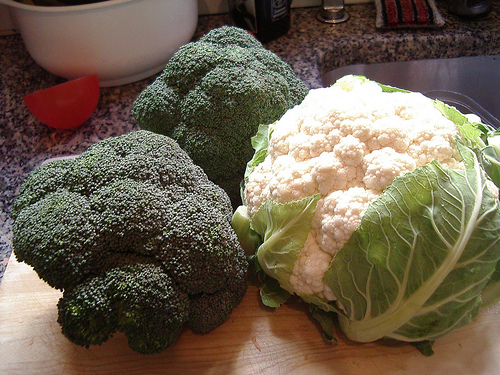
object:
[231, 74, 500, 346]
cauliflower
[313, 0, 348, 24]
dispensor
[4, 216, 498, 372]
board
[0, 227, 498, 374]
cutting board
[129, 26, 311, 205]
broccoli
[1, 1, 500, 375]
counter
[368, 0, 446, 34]
scrubber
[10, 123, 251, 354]
broccoli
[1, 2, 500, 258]
granite counter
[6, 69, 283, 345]
broccoli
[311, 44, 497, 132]
sink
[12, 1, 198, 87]
bowl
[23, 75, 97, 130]
tomato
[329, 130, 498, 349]
leaf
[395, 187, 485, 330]
vein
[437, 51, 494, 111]
wall